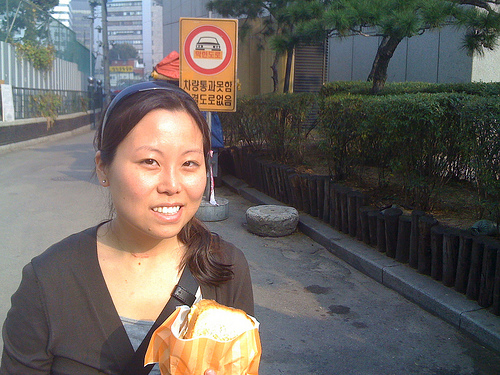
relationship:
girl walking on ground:
[5, 81, 270, 375] [0, 137, 495, 373]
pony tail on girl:
[178, 219, 233, 285] [5, 81, 258, 372]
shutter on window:
[298, 34, 330, 89] [115, 28, 123, 38]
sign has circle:
[178, 15, 239, 113] [186, 27, 231, 75]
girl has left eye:
[5, 81, 270, 375] [176, 153, 205, 177]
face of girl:
[100, 95, 211, 245] [5, 81, 270, 375]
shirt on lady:
[39, 250, 90, 320] [63, 74, 242, 357]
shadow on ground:
[307, 282, 348, 319] [8, 144, 495, 373]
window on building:
[135, 8, 142, 15] [100, 0, 156, 58]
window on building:
[117, 14, 138, 29] [88, 7, 160, 79]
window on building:
[107, 10, 113, 15] [92, 0, 162, 77]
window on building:
[128, 9, 134, 18] [91, 2, 168, 92]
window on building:
[98, 10, 118, 22] [90, 1, 145, 82]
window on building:
[107, 29, 112, 32] [88, 2, 165, 86]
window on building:
[115, 26, 139, 38] [88, 0, 158, 94]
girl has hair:
[5, 81, 270, 375] [103, 88, 232, 295]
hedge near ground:
[228, 93, 497, 185] [0, 137, 495, 373]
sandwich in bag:
[177, 291, 254, 349] [135, 322, 265, 372]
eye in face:
[135, 158, 160, 167] [100, 95, 211, 245]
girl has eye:
[5, 81, 270, 375] [135, 158, 160, 167]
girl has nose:
[5, 81, 270, 375] [151, 165, 184, 195]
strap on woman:
[163, 267, 195, 297] [4, 64, 267, 371]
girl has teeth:
[5, 81, 270, 375] [149, 204, 184, 216]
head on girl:
[94, 84, 210, 239] [5, 81, 270, 375]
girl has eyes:
[5, 81, 270, 375] [136, 137, 209, 182]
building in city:
[64, 2, 209, 114] [2, 0, 499, 372]